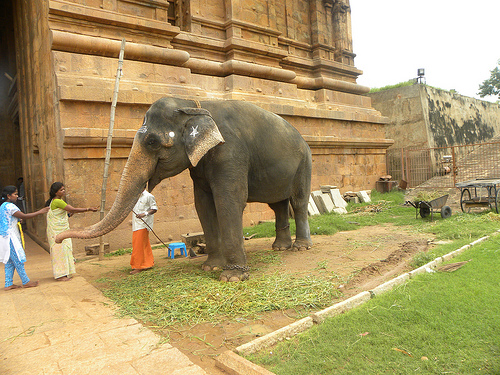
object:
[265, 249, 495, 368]
grass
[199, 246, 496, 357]
ground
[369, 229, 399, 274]
ground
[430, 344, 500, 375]
grass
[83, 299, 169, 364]
ground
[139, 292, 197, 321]
grass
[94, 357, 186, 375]
ground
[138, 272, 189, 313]
grass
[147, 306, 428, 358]
ground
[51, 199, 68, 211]
shirt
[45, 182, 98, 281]
woman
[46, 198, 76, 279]
sarong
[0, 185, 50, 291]
woman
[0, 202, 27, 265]
shirt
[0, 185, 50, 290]
design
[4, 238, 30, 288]
pants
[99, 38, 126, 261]
bamboo pole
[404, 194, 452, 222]
wheelbarrow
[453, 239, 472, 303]
grass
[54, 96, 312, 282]
elephant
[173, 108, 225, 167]
ear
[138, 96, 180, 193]
face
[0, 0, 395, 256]
building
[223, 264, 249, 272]
chain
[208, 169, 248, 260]
leg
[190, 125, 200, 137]
star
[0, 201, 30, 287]
indian outfit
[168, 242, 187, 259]
stool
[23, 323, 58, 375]
ground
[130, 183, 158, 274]
man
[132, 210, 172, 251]
stick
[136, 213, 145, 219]
hand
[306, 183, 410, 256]
pavers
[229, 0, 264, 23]
wall